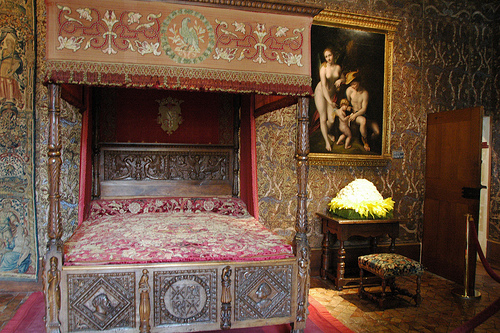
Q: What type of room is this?
A: Bedroom.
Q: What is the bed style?
A: Victorian.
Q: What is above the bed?
A: Canopy.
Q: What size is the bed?
A: Queen.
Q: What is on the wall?
A: Painting.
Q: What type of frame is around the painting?
A: Gold.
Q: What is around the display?
A: Ropes.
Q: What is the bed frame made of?
A: Wood.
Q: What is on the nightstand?
A: Lamp.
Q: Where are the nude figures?
A: On painting.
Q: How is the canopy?
A: Red and brown.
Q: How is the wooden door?
A: Open.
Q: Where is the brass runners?
A: On the velvet rope.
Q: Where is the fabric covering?
A: On stool.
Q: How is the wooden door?
A: Open.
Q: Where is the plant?
A: On table.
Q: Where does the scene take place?
A: In a bedroom.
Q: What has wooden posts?
A: The bed.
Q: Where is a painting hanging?
A: On the wall.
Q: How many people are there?
A: None.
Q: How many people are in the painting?
A: Three.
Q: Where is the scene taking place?
A: A bedroom.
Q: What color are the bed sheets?
A: Red and white.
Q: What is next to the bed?
A: A painting.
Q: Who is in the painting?
A: A man, a woman and a kid.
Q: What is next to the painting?
A: A bed.